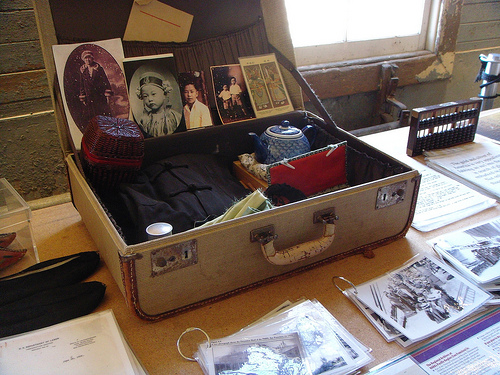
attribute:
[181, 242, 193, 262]
keyhole — rusty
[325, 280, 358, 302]
ring — silver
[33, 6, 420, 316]
carrying case — opened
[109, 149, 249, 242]
cloth — black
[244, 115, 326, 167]
teapot — blue, white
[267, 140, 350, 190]
lid — red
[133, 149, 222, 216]
shirt — black, traditional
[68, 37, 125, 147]
picture — black, white, toddler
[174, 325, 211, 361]
ring — silver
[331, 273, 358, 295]
ring — silver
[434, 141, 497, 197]
paper — white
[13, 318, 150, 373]
letterhead — business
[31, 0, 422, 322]
suitcase — old fashioned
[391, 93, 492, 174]
abacus — small, dark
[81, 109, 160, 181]
wicker box — small, red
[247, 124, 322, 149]
teapot — tiny, blue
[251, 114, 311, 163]
jar — blue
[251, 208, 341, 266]
handle — old, cracked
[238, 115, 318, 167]
teapot — blue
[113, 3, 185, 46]
envelope — brown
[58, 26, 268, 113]
pocket — fabric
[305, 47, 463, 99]
sill — wooden, worn